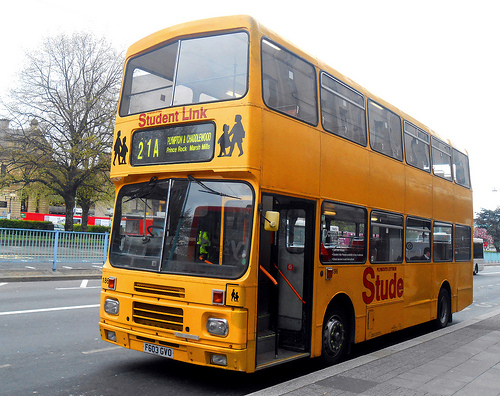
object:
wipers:
[120, 175, 157, 206]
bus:
[98, 13, 474, 373]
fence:
[0, 224, 108, 268]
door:
[255, 190, 315, 367]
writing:
[362, 267, 376, 306]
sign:
[136, 132, 212, 160]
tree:
[3, 35, 116, 241]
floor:
[107, 14, 475, 229]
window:
[107, 174, 252, 280]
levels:
[96, 186, 470, 374]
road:
[0, 264, 500, 396]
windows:
[259, 35, 319, 126]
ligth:
[103, 298, 119, 316]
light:
[205, 315, 230, 340]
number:
[137, 141, 145, 160]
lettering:
[183, 135, 185, 143]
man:
[227, 115, 245, 158]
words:
[182, 106, 189, 120]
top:
[107, 14, 473, 223]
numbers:
[155, 346, 159, 353]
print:
[361, 267, 405, 305]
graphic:
[112, 129, 128, 166]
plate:
[143, 342, 174, 359]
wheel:
[320, 303, 352, 365]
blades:
[190, 176, 246, 202]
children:
[113, 130, 123, 166]